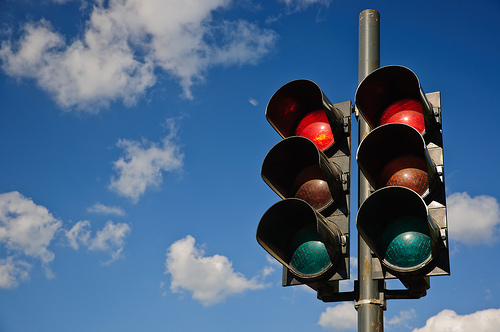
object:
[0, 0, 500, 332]
day time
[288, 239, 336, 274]
light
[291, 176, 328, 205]
light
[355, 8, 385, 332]
pole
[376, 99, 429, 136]
stop lights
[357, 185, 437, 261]
cases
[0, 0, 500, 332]
sky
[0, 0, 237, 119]
clouds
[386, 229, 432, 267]
lights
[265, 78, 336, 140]
casing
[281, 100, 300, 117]
shadow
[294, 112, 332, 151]
stop light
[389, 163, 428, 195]
yield light